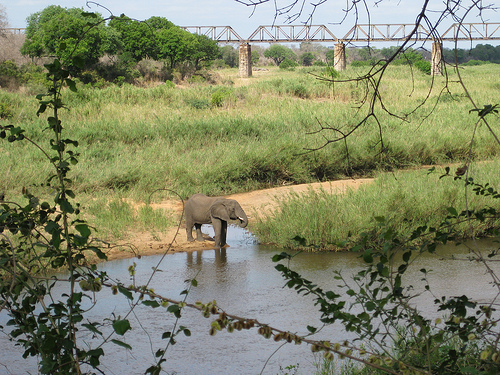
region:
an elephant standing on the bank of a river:
[177, 194, 250, 255]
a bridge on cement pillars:
[203, 14, 444, 83]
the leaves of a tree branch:
[31, 50, 88, 372]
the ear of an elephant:
[208, 200, 233, 225]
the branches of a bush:
[285, 220, 438, 349]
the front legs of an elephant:
[211, 222, 231, 254]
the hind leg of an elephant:
[181, 215, 206, 245]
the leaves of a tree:
[134, 23, 184, 54]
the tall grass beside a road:
[239, 130, 300, 189]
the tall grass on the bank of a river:
[284, 210, 341, 262]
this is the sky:
[205, 4, 223, 16]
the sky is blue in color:
[223, 2, 245, 17]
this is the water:
[202, 261, 239, 288]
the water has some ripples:
[206, 253, 247, 288]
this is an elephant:
[181, 192, 258, 253]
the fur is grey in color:
[194, 198, 210, 218]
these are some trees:
[26, 5, 227, 80]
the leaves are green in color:
[131, 22, 178, 52]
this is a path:
[240, 193, 260, 203]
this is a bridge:
[224, 23, 346, 68]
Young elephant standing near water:
[178, 192, 249, 250]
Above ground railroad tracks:
[4, 22, 497, 78]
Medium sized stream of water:
[0, 214, 495, 371]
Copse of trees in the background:
[19, 2, 225, 87]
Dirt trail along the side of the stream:
[212, 146, 498, 223]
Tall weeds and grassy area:
[4, 65, 495, 247]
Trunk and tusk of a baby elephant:
[235, 214, 248, 228]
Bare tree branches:
[230, 0, 491, 177]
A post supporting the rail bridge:
[235, 40, 252, 79]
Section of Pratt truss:
[247, 23, 336, 42]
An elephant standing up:
[173, 191, 251, 251]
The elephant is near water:
[169, 192, 247, 246]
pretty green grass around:
[3, 62, 494, 241]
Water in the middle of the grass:
[21, 218, 499, 373]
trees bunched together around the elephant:
[16, 9, 221, 83]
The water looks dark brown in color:
[15, 221, 493, 373]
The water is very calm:
[3, 215, 498, 362]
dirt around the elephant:
[0, 170, 385, 252]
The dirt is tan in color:
[14, 176, 401, 240]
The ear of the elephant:
[212, 203, 232, 223]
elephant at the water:
[177, 185, 245, 255]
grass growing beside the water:
[298, 170, 497, 231]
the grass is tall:
[281, 173, 497, 248]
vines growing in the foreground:
[26, 8, 166, 374]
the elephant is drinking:
[171, 193, 236, 249]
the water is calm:
[212, 268, 262, 314]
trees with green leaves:
[37, 19, 198, 63]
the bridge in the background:
[186, 19, 499, 51]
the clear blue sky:
[193, 8, 230, 18]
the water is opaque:
[225, 264, 271, 319]